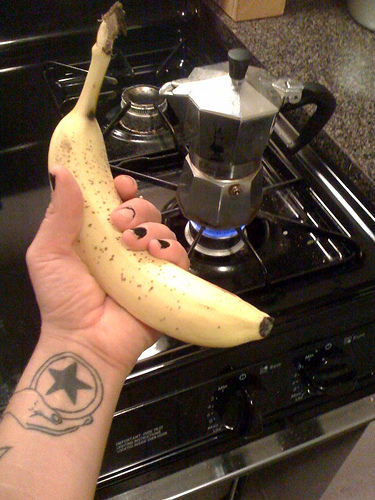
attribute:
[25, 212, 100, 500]
hand — holding, black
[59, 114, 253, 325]
bannana — yellow, ripe, brown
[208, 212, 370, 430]
stove — black, burning, round, lit, clean, blue, dark, on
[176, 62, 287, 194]
pot — silver, black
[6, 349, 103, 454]
tattoo — black